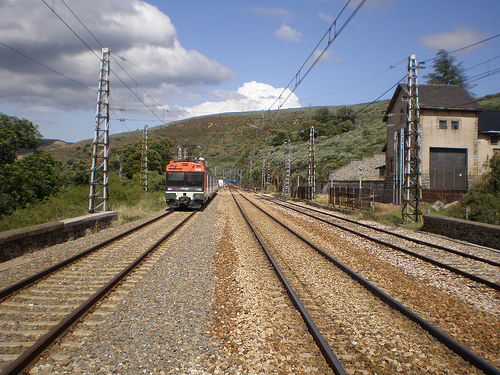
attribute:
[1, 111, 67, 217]
tree — green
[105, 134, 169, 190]
tree — green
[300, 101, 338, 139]
tree — green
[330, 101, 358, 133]
tree — green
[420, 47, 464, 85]
tree — green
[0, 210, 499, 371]
train tracks — made of metal, brown, dark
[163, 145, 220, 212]
train engine — orange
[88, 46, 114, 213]
tower — made of metal, for electricity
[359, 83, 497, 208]
building — old, beige, along train tracks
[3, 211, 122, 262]
wall — made of stone, small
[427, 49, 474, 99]
tree — a variety of pine, tall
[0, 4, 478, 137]
wire — for electricity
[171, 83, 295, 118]
cloud — white, fluffy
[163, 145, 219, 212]
train — moving, red, multicolored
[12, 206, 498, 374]
gravel — made of stones, next to train track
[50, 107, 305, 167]
hills — grassy, green, large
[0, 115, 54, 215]
tree — green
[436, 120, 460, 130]
windows — small, on a building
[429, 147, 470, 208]
door — large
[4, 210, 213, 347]
tracks — for the train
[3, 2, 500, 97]
sky — cloudy, blue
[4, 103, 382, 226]
trees — green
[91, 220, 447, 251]
metal — brown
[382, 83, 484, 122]
roof — brown